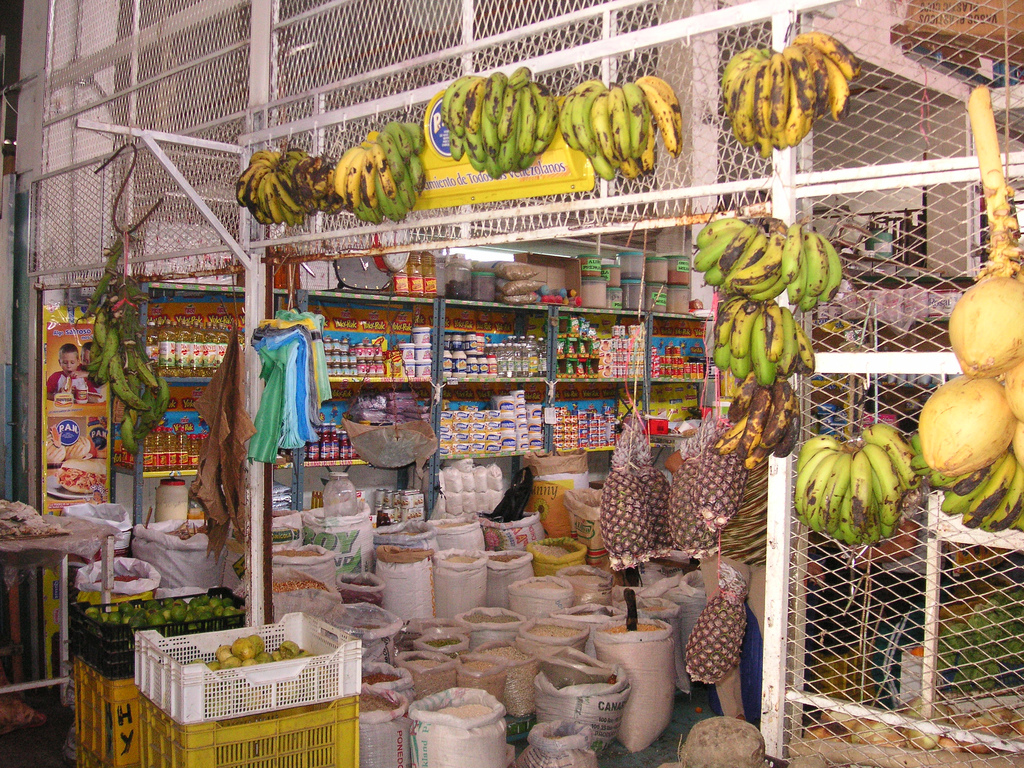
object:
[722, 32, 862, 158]
banana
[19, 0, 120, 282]
wall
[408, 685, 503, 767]
sack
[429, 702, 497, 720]
grain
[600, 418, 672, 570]
pineapple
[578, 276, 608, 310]
jar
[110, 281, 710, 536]
shelf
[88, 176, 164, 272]
hook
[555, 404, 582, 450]
canned goods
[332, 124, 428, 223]
bananas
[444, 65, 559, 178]
bananas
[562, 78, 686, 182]
bananas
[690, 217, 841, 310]
bananas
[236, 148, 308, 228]
bananas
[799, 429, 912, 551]
bananas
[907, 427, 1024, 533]
bananas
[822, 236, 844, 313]
banana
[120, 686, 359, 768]
crate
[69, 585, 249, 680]
crate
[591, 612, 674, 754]
sack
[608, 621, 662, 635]
spice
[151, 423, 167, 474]
bottle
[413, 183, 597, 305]
sign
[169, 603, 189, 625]
fruit